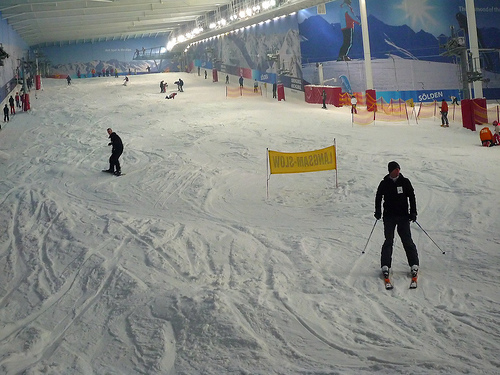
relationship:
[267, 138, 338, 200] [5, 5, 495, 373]
banner at event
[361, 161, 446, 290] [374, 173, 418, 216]
he in coat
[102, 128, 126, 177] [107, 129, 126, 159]
he in jacket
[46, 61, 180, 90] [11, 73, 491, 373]
people waiting to ski at slope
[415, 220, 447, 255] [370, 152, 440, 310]
pole held by man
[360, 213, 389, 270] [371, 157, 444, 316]
pole held by man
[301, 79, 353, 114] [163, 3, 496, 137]
barrier next to wall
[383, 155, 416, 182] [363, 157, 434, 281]
beanie used by skier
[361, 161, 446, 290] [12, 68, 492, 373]
he skiing on hill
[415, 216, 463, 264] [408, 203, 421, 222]
pole in hand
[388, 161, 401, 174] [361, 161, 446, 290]
beanie on he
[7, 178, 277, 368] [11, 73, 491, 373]
trail on slope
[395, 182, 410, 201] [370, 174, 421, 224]
square on coat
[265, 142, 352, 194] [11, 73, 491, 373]
banner on slope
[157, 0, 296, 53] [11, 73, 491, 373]
lights on slope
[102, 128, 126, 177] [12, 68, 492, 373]
he snowboarding down hill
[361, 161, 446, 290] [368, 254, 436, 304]
he on skiis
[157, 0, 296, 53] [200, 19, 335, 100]
lights on wall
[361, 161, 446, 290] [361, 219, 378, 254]
he with pole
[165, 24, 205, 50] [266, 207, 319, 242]
lights are white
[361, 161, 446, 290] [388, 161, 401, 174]
he wearing a beanie